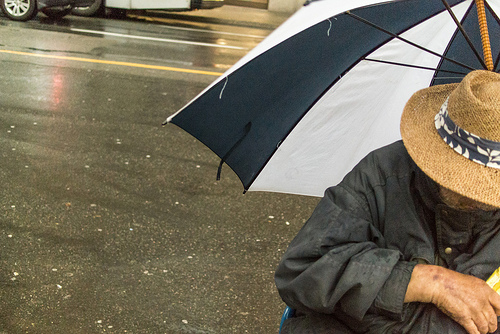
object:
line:
[0, 49, 224, 76]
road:
[0, 0, 323, 334]